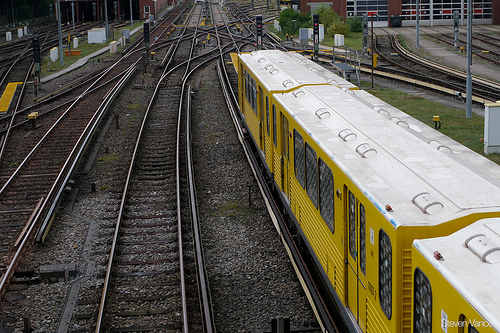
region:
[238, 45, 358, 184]
a yellow train passenger car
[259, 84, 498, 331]
a yellow train passenger car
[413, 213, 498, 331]
a yellow train passenger car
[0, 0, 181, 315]
a set of train tracks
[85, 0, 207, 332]
a set of train tracks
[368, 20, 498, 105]
a set of train tracks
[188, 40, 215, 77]
a set of train tracks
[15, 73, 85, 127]
a set of train tracks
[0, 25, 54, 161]
a set of train tracks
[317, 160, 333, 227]
a train passenger window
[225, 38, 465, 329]
A train with yellow cars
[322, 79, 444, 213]
The roof of train is painted white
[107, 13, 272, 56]
Many rails cross here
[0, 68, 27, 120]
Yellow paint on walkway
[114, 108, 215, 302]
Railroad tracks are made of steel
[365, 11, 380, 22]
Red paint on window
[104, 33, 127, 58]
White junction boxes for switches on rails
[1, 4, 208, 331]
No trains on these tracks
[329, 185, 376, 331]
Doors to train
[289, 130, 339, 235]
Windows on a trrain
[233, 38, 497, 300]
Roof of yellow train cars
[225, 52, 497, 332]
Yellow and white train cars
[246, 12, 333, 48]
Red lights on train tracks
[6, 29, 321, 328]
Multiple sets of train tracks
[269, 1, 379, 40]
Green bushes in front of building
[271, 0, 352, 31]
Red brick building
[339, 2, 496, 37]
Windows on red brick building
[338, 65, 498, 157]
Patch of green grass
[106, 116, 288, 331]
Gray gravel on train tracks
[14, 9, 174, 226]
Red gravel on train tracks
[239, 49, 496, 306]
The train is yellow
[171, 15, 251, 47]
The tracks are criss-crossing.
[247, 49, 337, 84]
The top of the train is white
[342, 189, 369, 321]
The doors to the train are yellow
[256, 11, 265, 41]
The light in the distance is red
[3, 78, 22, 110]
A yellow strip on the cement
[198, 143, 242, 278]
Gravel in between the tracks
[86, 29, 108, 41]
A white box in the corner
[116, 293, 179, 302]
Wooden slat as part of the train tracks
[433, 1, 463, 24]
Doors with checkered windows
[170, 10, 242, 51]
the tracks are crossing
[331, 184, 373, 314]
the train has a door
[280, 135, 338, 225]
the train has windows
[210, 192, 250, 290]
the gravel is gray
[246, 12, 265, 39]
the light is red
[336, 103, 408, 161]
the roof of the train is white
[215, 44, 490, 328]
the train is on tracks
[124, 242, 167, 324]
wood slates are in the tracks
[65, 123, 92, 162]
the tracks are metal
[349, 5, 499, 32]
the train station is close